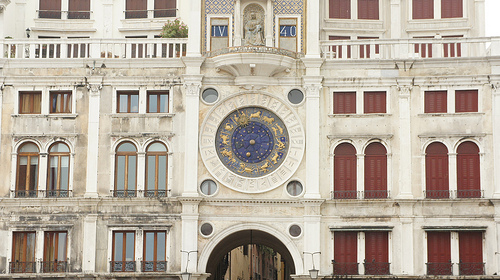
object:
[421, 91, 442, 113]
window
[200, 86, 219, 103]
circle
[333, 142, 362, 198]
window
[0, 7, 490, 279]
building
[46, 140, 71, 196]
window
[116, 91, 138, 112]
window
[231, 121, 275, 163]
design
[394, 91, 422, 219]
wall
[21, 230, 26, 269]
railing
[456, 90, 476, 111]
window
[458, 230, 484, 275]
window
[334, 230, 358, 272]
window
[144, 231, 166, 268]
window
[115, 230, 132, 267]
window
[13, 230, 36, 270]
window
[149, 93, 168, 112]
window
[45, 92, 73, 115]
window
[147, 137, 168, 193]
window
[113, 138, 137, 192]
window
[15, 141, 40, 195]
window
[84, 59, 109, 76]
design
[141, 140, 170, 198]
window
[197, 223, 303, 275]
arch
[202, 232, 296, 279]
doorway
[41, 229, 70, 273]
window